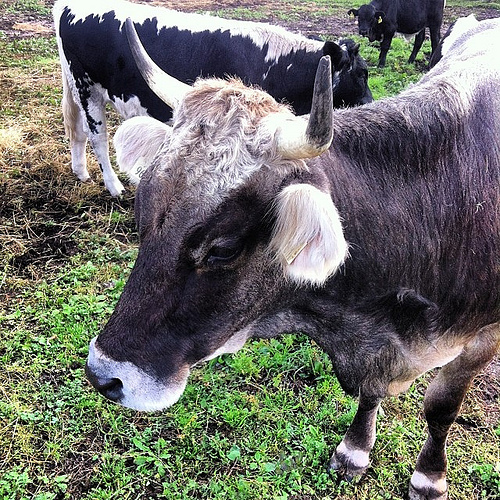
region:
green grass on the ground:
[308, 430, 327, 459]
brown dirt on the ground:
[70, 456, 92, 483]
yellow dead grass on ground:
[36, 146, 62, 182]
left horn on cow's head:
[290, 58, 344, 162]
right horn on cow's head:
[120, 15, 197, 104]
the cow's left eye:
[199, 229, 259, 277]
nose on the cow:
[83, 362, 121, 399]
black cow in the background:
[352, 0, 449, 64]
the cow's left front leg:
[401, 379, 464, 495]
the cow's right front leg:
[323, 388, 377, 498]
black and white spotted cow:
[54, 10, 374, 195]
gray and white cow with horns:
[87, 20, 493, 498]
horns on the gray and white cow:
[125, 19, 332, 156]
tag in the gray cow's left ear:
[276, 231, 310, 264]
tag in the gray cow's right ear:
[130, 158, 150, 178]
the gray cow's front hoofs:
[323, 440, 447, 498]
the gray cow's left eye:
[207, 242, 236, 258]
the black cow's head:
[347, 5, 383, 36]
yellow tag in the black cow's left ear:
[375, 15, 383, 23]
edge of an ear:
[320, 233, 344, 310]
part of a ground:
[258, 400, 292, 453]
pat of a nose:
[86, 369, 159, 443]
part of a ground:
[226, 404, 260, 458]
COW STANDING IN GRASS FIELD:
[112, 77, 491, 471]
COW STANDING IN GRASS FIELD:
[57, 18, 230, 84]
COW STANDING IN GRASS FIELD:
[352, 5, 441, 41]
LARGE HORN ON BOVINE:
[294, 82, 367, 185]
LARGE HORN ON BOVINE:
[116, 29, 198, 116]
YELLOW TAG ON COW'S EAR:
[377, 16, 384, 28]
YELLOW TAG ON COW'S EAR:
[345, 7, 364, 22]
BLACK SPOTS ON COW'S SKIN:
[89, 26, 326, 165]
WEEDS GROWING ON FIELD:
[143, 432, 283, 462]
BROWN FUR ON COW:
[352, 176, 476, 301]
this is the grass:
[379, 67, 401, 92]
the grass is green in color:
[223, 390, 273, 432]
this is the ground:
[76, 445, 94, 470]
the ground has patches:
[50, 436, 122, 471]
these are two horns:
[117, 15, 333, 158]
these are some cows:
[43, 4, 498, 418]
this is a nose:
[83, 363, 125, 394]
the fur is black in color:
[409, 263, 454, 315]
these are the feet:
[348, 399, 466, 494]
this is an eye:
[203, 234, 245, 265]